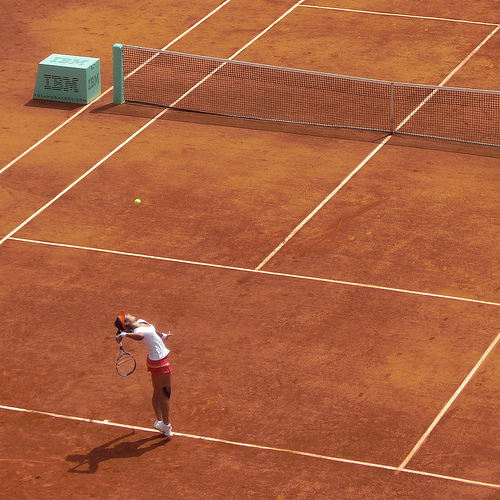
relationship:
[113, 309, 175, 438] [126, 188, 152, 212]
lady serving ball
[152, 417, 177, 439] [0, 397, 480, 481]
shoes behind lines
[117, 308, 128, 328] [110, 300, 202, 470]
visor on woman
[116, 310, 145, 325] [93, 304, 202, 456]
hair on woman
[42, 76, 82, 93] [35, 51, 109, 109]
logo on box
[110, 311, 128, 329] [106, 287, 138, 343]
visor on head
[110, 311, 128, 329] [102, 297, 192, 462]
visor on woman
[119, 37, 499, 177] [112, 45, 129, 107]
net on net frame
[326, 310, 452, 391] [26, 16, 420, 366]
prints on court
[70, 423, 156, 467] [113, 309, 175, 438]
shadow behind lady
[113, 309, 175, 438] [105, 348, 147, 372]
lady raising racket